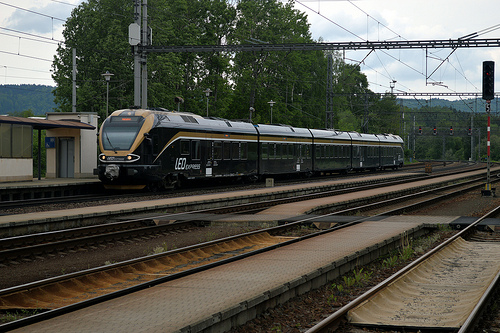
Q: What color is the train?
A: Black and yellow.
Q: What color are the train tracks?
A: Brown.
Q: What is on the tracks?
A: The train.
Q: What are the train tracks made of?
A: Metal.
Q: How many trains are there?
A: One.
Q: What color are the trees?
A: Green.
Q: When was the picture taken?
A: Daytime.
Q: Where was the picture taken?
A: On a bridge.